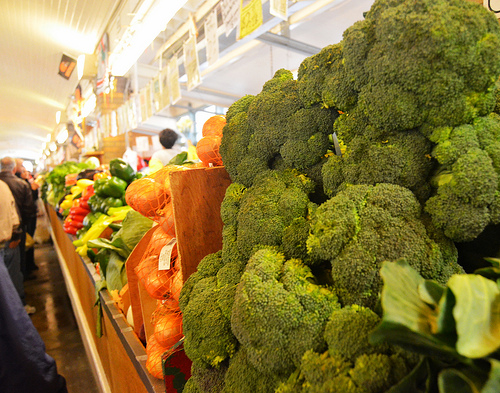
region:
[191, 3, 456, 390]
The bunch of broccoli on the stand.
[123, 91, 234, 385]
The bags of onions on the stand.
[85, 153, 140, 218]
The green peppers on the stand.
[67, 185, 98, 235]
The red peppers on the stand.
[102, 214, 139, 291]
The lettuce next to the onions.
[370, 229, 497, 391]
The lettuce leaves to the right of the broccoli.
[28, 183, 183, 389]
The stand the produce items are placed on.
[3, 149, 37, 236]
The older man in the black jacket standing in line.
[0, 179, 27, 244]
The person in the beige jacket standing in line.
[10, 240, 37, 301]
The blue jeans the older man in the black jacket is wearing.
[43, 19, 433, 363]
Produce section at grocery store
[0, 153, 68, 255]
People at a market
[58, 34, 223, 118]
Signs at a store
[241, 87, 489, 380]
Large section of broccoli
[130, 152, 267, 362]
Bags of yellow onions next to broccoli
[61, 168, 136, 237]
Carrots next to bell peppers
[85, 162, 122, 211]
Bell peppers are green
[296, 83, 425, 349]
Broccoli is green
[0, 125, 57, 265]
people standing in a line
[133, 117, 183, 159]
Person on the other side of produce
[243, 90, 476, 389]
the brocooli is green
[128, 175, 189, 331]
the oranges are orange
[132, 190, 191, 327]
the oranges are in a net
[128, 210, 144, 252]
the cabbage is green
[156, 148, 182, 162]
the shirt is white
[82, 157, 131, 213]
the green pepper is green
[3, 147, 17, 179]
his head is bald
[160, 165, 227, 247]
the frame is brown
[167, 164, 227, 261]
the frame is wooden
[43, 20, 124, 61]
light is on the ceeling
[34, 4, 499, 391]
display of vegetables for sale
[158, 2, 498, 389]
green broccoli florets piled high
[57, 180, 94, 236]
a pile of red bell peppers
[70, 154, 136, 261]
green bell peppers for sale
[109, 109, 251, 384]
onions in an orange string bag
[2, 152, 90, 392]
people in the produce aisle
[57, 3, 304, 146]
prices are written on notes above the produce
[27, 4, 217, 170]
bright lights illuminate the shopping aisle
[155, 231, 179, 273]
a label on a bag of onions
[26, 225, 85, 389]
shiny floor of a produce aisle in a store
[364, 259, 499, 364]
leafy green vegetable inside store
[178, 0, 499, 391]
green broccholi piled high in grocery store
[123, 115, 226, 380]
bagged brown onions on produce aisle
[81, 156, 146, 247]
green bell peppers on produce aisle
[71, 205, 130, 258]
yellow zucchini squash on produce aisle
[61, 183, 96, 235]
red bell peppers stacked on produce aisle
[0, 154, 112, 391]
people walking down produce aisle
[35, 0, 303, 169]
pricing signs hanging above produce aisle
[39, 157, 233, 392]
fully loaded wooden produce bins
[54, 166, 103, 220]
large dark purple eggplants in produce bin